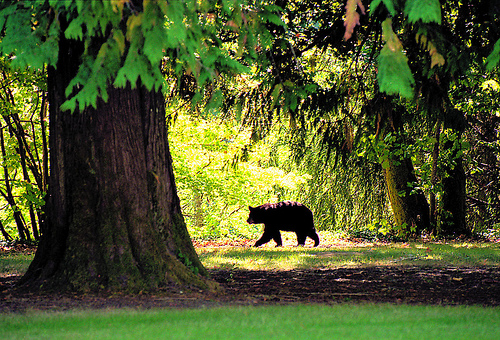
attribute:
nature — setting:
[185, 177, 360, 247]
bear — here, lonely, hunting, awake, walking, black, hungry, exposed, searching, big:
[246, 202, 321, 250]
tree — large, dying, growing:
[28, 1, 225, 307]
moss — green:
[84, 164, 105, 180]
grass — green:
[18, 310, 467, 329]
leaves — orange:
[379, 23, 445, 68]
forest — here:
[6, 3, 498, 338]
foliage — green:
[4, 3, 458, 101]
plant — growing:
[364, 216, 418, 240]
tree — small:
[5, 114, 44, 234]